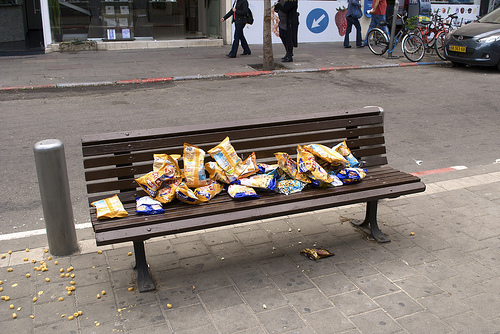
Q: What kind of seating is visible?
A: Bench.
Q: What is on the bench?
A: Bags of snacks.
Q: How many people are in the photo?
A: Four.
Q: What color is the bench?
A: Brown.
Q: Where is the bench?
A: Sidewalk.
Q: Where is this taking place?
A: Along a city street.